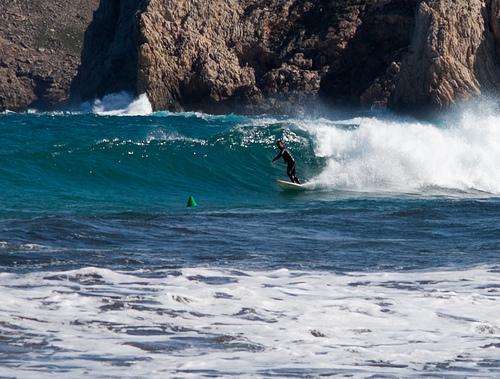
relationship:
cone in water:
[181, 192, 201, 215] [0, 96, 499, 378]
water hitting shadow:
[0, 96, 499, 378] [69, 0, 154, 120]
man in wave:
[271, 141, 302, 184] [55, 122, 491, 192]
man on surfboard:
[270, 135, 303, 188] [275, 179, 306, 199]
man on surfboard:
[271, 141, 302, 184] [275, 179, 306, 199]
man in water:
[271, 141, 302, 184] [0, 96, 499, 378]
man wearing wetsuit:
[271, 141, 302, 184] [276, 148, 305, 183]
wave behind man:
[55, 122, 491, 192] [270, 135, 303, 188]